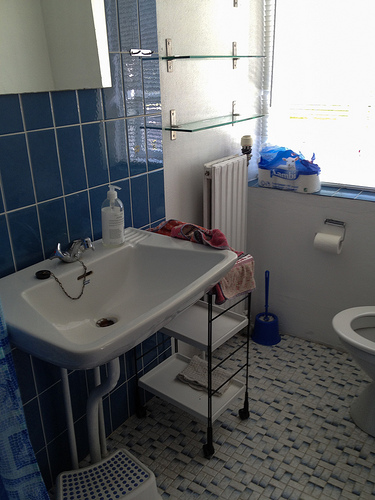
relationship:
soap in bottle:
[100, 223, 128, 246] [98, 184, 129, 247]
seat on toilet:
[330, 301, 375, 360] [331, 301, 374, 442]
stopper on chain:
[35, 269, 53, 281] [50, 258, 87, 301]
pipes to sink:
[85, 358, 123, 466] [0, 207, 238, 372]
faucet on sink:
[47, 238, 97, 267] [0, 207, 238, 372]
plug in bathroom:
[35, 269, 53, 281] [1, 0, 374, 500]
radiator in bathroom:
[202, 153, 253, 333] [1, 0, 374, 500]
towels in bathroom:
[145, 218, 258, 305] [1, 0, 374, 500]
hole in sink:
[93, 315, 119, 329] [0, 207, 238, 372]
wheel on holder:
[201, 442, 216, 458] [130, 249, 259, 458]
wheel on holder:
[238, 407, 250, 422] [130, 249, 259, 458]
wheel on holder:
[134, 406, 150, 421] [130, 249, 259, 458]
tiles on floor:
[54, 323, 373, 498] [3, 319, 374, 499]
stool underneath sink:
[55, 443, 163, 500] [0, 207, 238, 372]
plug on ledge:
[35, 269, 53, 281] [0, 225, 148, 295]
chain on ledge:
[50, 258, 87, 301] [0, 225, 148, 295]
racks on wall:
[153, 37, 272, 130] [0, 0, 265, 499]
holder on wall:
[312, 219, 351, 253] [243, 186, 372, 358]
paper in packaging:
[258, 138, 325, 193] [259, 141, 324, 192]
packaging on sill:
[259, 141, 324, 192] [247, 169, 374, 204]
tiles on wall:
[0, 2, 173, 499] [0, 0, 265, 499]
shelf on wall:
[154, 53, 269, 59] [0, 0, 265, 499]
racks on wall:
[159, 103, 264, 137] [0, 0, 265, 499]